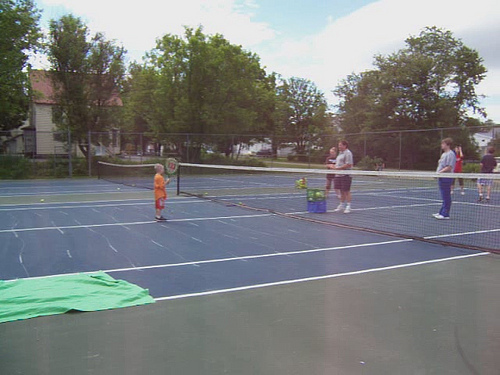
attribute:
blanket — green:
[3, 270, 158, 325]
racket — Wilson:
[165, 156, 177, 181]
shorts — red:
[152, 191, 167, 215]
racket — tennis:
[150, 136, 187, 190]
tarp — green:
[4, 265, 160, 324]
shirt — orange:
[150, 174, 167, 200]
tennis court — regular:
[2, 174, 499, 374]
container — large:
[307, 179, 332, 217]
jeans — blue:
[434, 177, 453, 216]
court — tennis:
[0, 187, 485, 323]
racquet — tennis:
[160, 153, 180, 178]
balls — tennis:
[304, 185, 322, 203]